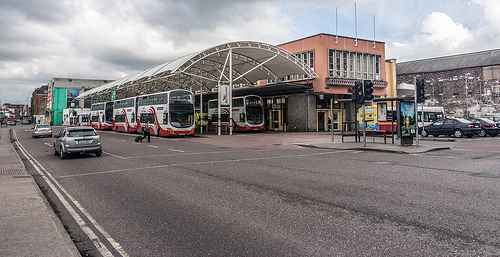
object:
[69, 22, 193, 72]
cloud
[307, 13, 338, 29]
sky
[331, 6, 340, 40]
pole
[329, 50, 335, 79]
window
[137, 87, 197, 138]
bus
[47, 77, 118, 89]
roof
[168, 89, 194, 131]
front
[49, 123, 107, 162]
car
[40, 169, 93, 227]
line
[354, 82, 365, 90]
light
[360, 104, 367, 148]
pole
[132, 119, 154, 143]
person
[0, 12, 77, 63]
cloud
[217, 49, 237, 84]
frame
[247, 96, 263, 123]
window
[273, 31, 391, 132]
station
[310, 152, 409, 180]
street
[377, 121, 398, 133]
object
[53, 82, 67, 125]
object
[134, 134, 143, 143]
luggage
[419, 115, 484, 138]
car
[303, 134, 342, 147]
stop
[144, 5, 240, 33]
cloud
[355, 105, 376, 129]
advertisement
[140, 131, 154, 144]
pants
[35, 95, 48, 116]
building